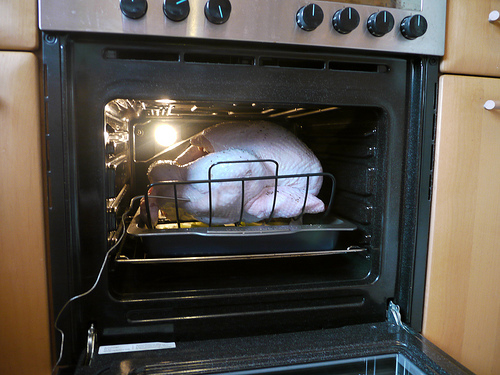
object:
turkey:
[135, 121, 326, 225]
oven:
[39, 34, 437, 334]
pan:
[125, 219, 355, 252]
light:
[152, 124, 176, 148]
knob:
[295, 3, 324, 31]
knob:
[332, 7, 358, 34]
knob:
[369, 9, 395, 37]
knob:
[484, 98, 498, 111]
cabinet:
[417, 74, 500, 372]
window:
[226, 357, 417, 374]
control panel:
[37, 1, 446, 55]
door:
[110, 319, 468, 375]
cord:
[45, 226, 128, 327]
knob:
[205, 1, 232, 25]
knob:
[399, 15, 425, 40]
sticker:
[98, 341, 177, 354]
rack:
[117, 161, 367, 229]